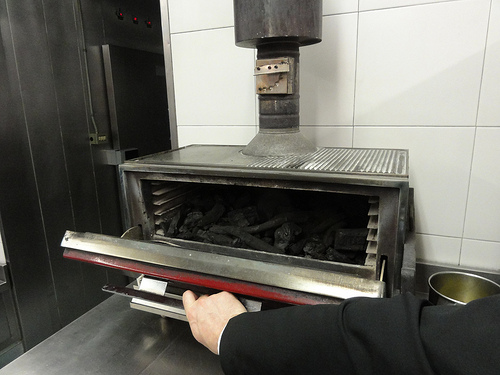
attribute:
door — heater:
[71, 217, 377, 312]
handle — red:
[119, 280, 213, 325]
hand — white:
[180, 287, 247, 351]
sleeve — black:
[217, 292, 497, 374]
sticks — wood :
[163, 191, 364, 258]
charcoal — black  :
[164, 197, 366, 261]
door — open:
[57, 229, 388, 336]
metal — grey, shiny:
[126, 328, 173, 370]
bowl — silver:
[426, 270, 498, 304]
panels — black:
[7, 9, 101, 208]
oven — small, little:
[114, 120, 437, 311]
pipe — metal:
[233, 2, 322, 157]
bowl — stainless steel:
[431, 264, 499, 309]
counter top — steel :
[0, 278, 431, 373]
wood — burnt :
[166, 202, 346, 244]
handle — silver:
[93, 278, 266, 355]